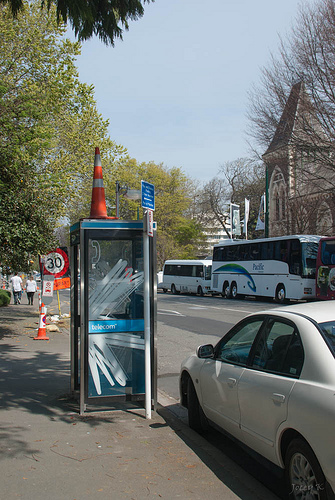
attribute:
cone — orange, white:
[85, 142, 113, 235]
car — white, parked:
[197, 320, 326, 446]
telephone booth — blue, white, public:
[65, 226, 164, 404]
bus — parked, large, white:
[205, 236, 325, 303]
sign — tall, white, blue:
[134, 181, 168, 217]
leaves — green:
[8, 314, 30, 339]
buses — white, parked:
[146, 246, 326, 297]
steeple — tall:
[277, 76, 335, 156]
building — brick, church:
[243, 87, 334, 245]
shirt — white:
[11, 276, 19, 292]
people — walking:
[6, 269, 41, 307]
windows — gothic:
[259, 169, 292, 229]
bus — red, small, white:
[159, 257, 212, 293]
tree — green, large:
[111, 153, 219, 265]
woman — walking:
[21, 266, 36, 306]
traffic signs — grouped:
[27, 236, 81, 337]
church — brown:
[214, 140, 332, 233]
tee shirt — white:
[24, 282, 35, 294]